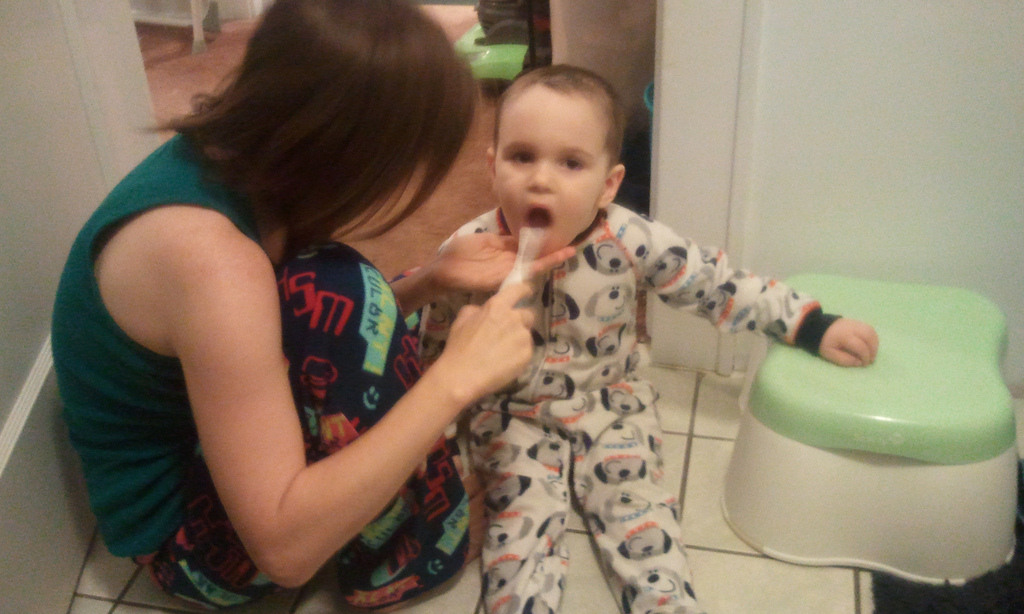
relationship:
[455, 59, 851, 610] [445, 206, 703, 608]
boy wearing pajamas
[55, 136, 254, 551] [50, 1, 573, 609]
shirt on woman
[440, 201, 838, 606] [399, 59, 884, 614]
pajamas on boy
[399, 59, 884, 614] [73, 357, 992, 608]
boy on floor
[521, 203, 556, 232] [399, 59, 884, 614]
mouth of boy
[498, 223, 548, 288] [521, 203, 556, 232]
brush in mouth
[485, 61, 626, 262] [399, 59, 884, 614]
head belonging to boy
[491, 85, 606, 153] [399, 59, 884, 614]
forehead belonging to boy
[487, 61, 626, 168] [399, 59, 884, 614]
hair belonging to boy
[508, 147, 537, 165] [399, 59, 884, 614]
eye belonging to boy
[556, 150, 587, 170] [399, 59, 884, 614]
eye belonging to boy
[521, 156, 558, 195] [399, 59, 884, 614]
nose belonging to boy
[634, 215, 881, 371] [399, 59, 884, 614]
arm belonging to boy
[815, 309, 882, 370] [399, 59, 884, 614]
hand belonging to boy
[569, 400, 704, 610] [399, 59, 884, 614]
left leg belonging to boy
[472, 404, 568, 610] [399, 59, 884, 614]
right leg belonging to boy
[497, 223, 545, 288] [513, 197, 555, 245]
brush going in mouth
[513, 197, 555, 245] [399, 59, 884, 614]
mouth belonging to boy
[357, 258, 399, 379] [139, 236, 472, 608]
patch printed on pants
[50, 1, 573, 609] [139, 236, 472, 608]
woman wearing pants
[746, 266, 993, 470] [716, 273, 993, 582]
seat cover covering seat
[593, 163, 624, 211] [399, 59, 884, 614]
left ear belonging to boy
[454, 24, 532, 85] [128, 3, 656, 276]
paper lying in background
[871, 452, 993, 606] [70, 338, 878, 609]
carpet partially covering tile